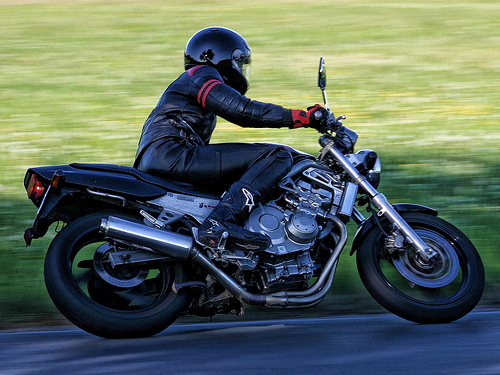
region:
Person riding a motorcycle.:
[18, 12, 494, 367]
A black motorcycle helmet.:
[178, 15, 262, 92]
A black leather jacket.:
[128, 62, 313, 146]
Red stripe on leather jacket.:
[182, 67, 237, 122]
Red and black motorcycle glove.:
[286, 91, 322, 134]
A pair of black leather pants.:
[143, 137, 302, 204]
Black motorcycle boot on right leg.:
[207, 170, 277, 257]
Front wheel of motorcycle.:
[355, 185, 497, 343]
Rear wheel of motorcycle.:
[39, 199, 194, 346]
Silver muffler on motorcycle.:
[88, 213, 208, 270]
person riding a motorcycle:
[5, 21, 498, 348]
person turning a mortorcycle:
[10, 20, 493, 350]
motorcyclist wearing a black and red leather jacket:
[124, 17, 343, 253]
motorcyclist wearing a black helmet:
[120, 19, 337, 260]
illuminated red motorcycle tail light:
[15, 164, 59, 211]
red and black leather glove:
[285, 95, 328, 135]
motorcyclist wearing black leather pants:
[118, 19, 353, 253]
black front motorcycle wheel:
[352, 194, 492, 331]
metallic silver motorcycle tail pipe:
[92, 212, 198, 266]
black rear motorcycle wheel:
[41, 205, 201, 348]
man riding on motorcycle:
[15, 12, 494, 358]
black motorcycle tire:
[42, 205, 198, 346]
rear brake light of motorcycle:
[15, 155, 71, 252]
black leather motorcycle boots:
[202, 175, 273, 279]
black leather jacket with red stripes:
[134, 56, 295, 162]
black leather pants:
[132, 120, 300, 211]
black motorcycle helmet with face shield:
[176, 10, 253, 100]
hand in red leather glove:
[285, 95, 331, 136]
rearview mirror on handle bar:
[305, 42, 336, 112]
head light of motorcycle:
[337, 116, 400, 211]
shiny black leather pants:
[130, 129, 301, 199]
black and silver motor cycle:
[13, 59, 493, 349]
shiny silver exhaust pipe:
[88, 213, 202, 263]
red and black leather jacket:
[134, 59, 329, 161]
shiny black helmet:
[184, 24, 251, 93]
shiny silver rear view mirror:
[310, 57, 337, 97]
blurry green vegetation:
[4, 2, 499, 325]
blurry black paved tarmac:
[1, 306, 495, 373]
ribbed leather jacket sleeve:
[188, 69, 299, 137]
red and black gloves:
[285, 99, 331, 136]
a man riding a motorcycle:
[10, 7, 485, 338]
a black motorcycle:
[18, 118, 488, 330]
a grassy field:
[19, 7, 499, 304]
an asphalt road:
[8, 317, 495, 372]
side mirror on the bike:
[298, 42, 359, 113]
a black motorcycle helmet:
[170, 9, 270, 87]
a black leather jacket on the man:
[101, 51, 286, 154]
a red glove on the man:
[289, 96, 332, 138]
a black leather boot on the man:
[194, 169, 299, 251]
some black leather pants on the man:
[135, 127, 292, 200]